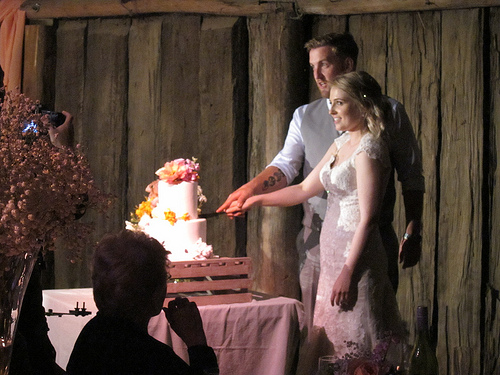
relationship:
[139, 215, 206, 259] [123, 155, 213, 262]
tier on cake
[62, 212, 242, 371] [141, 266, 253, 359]
person raising hand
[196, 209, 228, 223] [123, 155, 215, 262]
knife cutting cake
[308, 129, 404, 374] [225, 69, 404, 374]
dress of bride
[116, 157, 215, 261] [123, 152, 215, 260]
flower decorations on wedding cake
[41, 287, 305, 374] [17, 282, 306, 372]
cloth on table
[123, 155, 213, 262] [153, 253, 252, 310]
cake on crate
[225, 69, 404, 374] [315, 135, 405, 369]
bride wearing dress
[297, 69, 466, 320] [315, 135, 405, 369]
bride wearing dress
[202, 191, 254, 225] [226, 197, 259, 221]
hand on top of hand